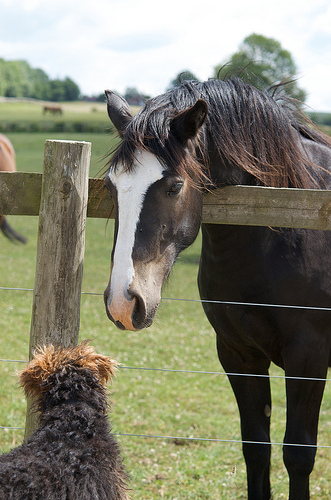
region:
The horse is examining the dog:
[12, 73, 236, 423]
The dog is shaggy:
[21, 330, 131, 498]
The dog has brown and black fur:
[9, 331, 133, 491]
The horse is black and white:
[59, 68, 323, 339]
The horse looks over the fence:
[5, 130, 322, 435]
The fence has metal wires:
[5, 277, 330, 469]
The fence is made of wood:
[2, 131, 320, 376]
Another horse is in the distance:
[28, 82, 83, 125]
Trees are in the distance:
[8, 51, 88, 102]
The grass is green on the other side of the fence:
[8, 230, 222, 425]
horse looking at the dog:
[10, 97, 241, 465]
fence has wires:
[96, 237, 329, 437]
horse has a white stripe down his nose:
[116, 153, 153, 315]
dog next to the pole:
[20, 319, 123, 498]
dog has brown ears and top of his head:
[25, 344, 108, 389]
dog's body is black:
[0, 368, 127, 498]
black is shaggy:
[18, 339, 132, 496]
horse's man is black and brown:
[151, 77, 329, 201]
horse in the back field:
[46, 96, 83, 128]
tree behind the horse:
[203, 22, 307, 113]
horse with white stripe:
[102, 115, 208, 334]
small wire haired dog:
[22, 341, 122, 496]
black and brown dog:
[6, 350, 117, 497]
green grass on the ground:
[117, 378, 220, 440]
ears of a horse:
[103, 84, 215, 153]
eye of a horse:
[160, 169, 192, 200]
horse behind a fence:
[96, 83, 321, 415]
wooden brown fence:
[15, 121, 322, 433]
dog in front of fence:
[6, 345, 127, 483]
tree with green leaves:
[220, 32, 303, 90]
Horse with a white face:
[96, 101, 281, 352]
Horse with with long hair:
[167, 90, 297, 181]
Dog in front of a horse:
[25, 335, 151, 474]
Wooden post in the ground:
[33, 137, 106, 449]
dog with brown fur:
[14, 332, 112, 391]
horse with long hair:
[187, 99, 282, 192]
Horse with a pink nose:
[98, 271, 168, 358]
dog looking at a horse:
[30, 347, 123, 414]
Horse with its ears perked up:
[92, 80, 216, 168]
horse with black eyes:
[162, 171, 188, 202]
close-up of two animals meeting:
[13, 51, 302, 455]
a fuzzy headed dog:
[13, 336, 122, 476]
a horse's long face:
[107, 139, 190, 322]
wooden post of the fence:
[30, 131, 92, 284]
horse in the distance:
[37, 100, 61, 115]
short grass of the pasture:
[128, 380, 214, 417]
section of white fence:
[0, 92, 41, 102]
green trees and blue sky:
[3, 17, 78, 87]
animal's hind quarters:
[0, 118, 23, 241]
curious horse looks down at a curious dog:
[10, 56, 292, 459]